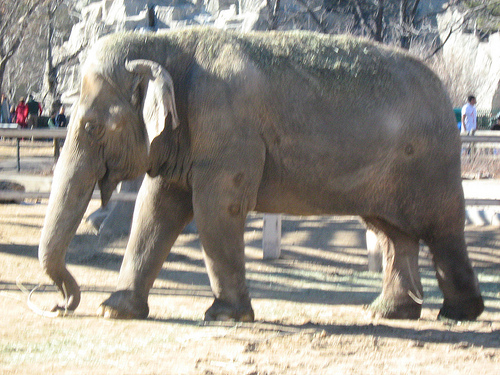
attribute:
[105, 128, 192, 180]
skin — Wrinkled, grey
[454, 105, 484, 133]
shirt — white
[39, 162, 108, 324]
trunk — long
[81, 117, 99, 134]
eye — closed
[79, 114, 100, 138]
eye — small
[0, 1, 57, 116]
trees — dead, brown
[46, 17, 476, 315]
elephant — large, grey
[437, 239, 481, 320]
legs — small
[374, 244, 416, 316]
legs — small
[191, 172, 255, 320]
legs — small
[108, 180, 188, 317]
legs — small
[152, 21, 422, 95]
mat — green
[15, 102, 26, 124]
jacket — red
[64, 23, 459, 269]
elephant — grey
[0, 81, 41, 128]
woman — wearing red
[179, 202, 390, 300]
shadow — black